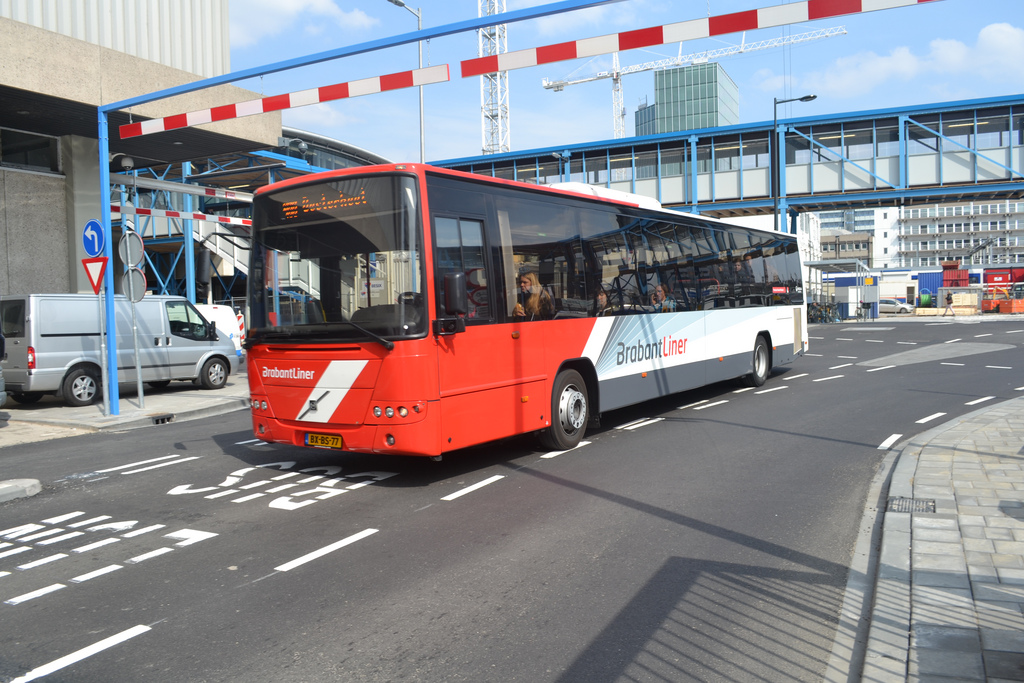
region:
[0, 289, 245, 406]
A silver van on the road.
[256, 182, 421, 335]
A large windshield on a bus front.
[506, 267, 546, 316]
A blonde woman in a bus.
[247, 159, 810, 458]
An orange and white bus.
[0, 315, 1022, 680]
A grey paved road with white lines.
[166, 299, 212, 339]
Passenger window on the grey van.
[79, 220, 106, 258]
A blue circle with left pointing arrow.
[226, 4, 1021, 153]
A baby blue sky with white clouds.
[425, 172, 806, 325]
Black windows coming down the broad side of the bus.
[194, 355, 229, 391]
Front passenger tire on a silver van.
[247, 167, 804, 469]
orange and white bus on the street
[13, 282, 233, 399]
silver van on the street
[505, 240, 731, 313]
people riding on the bus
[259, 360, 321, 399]
white lettering on the bus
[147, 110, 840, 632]
a bus on the road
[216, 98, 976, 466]
white design on the bus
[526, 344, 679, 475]
black wheels on the bus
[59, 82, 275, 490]
blue pole on the road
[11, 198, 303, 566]
grey car parked in thebackground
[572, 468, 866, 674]
shadows on the ground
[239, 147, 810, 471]
Red white and blue bus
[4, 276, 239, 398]
Parked grey van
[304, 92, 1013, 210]
Blue pedestrian overpass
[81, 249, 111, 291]
Red and white yield sign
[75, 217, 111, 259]
Blue arrow sign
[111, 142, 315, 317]
Blue scaffolding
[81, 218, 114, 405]
Two traffic signs on a pole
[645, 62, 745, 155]
Tall building with many windows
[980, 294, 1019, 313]
Orange construction barriers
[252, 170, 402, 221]
Orange writing on the bus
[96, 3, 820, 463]
red and white bus under a blue pole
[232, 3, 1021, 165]
sky is blue and cloudy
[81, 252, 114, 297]
red and white triangular sign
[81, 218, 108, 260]
white arrow on round blue sign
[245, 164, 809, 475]
yellow license plate on the bus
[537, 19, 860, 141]
white crane next to building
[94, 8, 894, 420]
red and white striped boards hanging from blue pole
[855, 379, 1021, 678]
sidewalk is paved